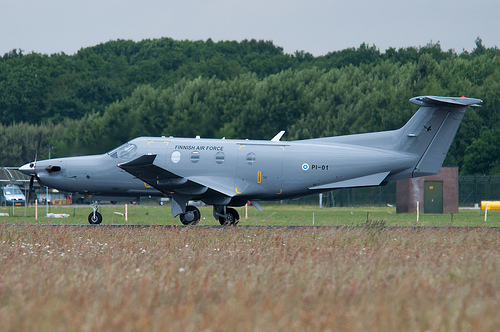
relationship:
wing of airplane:
[128, 156, 246, 200] [6, 116, 439, 234]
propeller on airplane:
[13, 153, 54, 171] [6, 116, 439, 234]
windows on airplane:
[168, 143, 261, 175] [6, 116, 439, 234]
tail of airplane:
[393, 79, 469, 145] [6, 116, 439, 234]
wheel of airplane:
[174, 204, 209, 234] [6, 116, 439, 234]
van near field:
[0, 186, 48, 204] [129, 255, 247, 312]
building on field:
[2, 177, 20, 183] [129, 255, 247, 312]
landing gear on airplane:
[84, 192, 134, 217] [6, 116, 439, 234]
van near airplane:
[0, 186, 48, 204] [6, 116, 439, 234]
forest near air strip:
[94, 54, 260, 112] [280, 211, 322, 243]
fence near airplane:
[129, 222, 153, 230] [6, 116, 439, 234]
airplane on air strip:
[6, 116, 439, 234] [280, 211, 322, 243]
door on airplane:
[36, 192, 51, 204] [6, 116, 439, 234]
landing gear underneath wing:
[84, 192, 134, 217] [128, 156, 246, 200]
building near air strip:
[2, 177, 20, 183] [280, 211, 322, 243]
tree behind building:
[12, 71, 70, 95] [2, 177, 20, 183]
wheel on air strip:
[174, 204, 209, 234] [280, 211, 322, 243]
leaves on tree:
[305, 34, 372, 88] [12, 71, 70, 95]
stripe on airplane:
[235, 132, 315, 160] [6, 116, 439, 234]